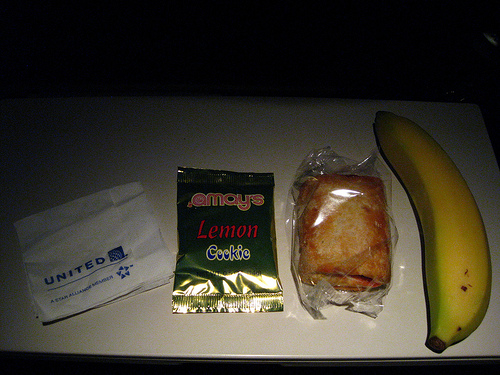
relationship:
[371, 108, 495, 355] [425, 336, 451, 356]
banana has stem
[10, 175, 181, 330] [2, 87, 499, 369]
napkin on table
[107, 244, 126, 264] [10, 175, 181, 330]
logo on napkin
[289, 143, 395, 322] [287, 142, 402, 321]
dessert in plastic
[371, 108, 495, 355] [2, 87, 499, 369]
banana on table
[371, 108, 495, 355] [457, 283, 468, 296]
banana has spot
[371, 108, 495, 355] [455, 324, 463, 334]
banana has spot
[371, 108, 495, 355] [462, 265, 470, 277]
banana has spot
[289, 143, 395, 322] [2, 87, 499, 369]
dessert on table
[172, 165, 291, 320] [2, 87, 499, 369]
cookie package on table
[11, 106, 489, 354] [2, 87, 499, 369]
food on table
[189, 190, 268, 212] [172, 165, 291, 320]
brand name on cookie package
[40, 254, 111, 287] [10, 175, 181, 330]
airline name on napkin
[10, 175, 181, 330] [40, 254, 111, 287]
napkin has airline name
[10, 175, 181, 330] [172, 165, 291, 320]
napkin next to cookie package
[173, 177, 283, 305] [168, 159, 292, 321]
food in cookie package